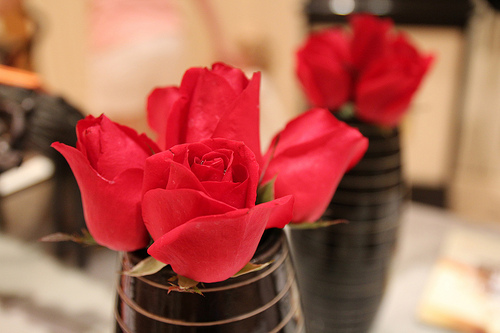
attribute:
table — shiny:
[13, 198, 500, 329]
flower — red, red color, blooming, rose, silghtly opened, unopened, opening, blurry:
[263, 121, 344, 219]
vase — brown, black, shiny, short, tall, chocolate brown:
[116, 235, 303, 333]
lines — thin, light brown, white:
[118, 248, 293, 294]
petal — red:
[313, 134, 359, 183]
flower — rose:
[153, 139, 279, 285]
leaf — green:
[287, 216, 349, 235]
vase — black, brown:
[288, 111, 410, 331]